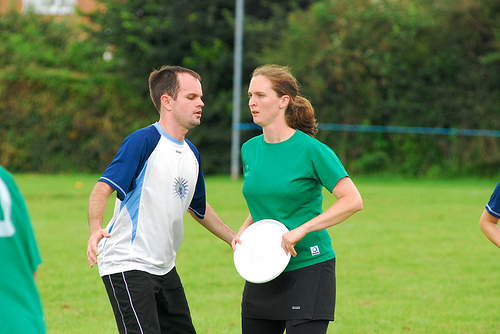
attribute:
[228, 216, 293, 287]
frisbee — white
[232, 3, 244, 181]
pole — blue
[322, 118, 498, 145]
pole — blue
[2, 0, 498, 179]
trees — background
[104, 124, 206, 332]
attire — bottom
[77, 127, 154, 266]
arms — extended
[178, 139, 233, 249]
arms — extended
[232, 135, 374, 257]
shirt — green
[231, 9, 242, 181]
pole — metal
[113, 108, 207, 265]
shirt — blue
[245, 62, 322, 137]
hair — red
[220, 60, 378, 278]
t-shirt — green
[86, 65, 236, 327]
man — grabbing, trying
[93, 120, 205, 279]
shirt — blue, white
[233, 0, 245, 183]
pole — silver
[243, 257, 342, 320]
attire — bottom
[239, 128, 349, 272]
shirt — green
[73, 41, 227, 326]
person — standing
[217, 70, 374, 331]
person — standing